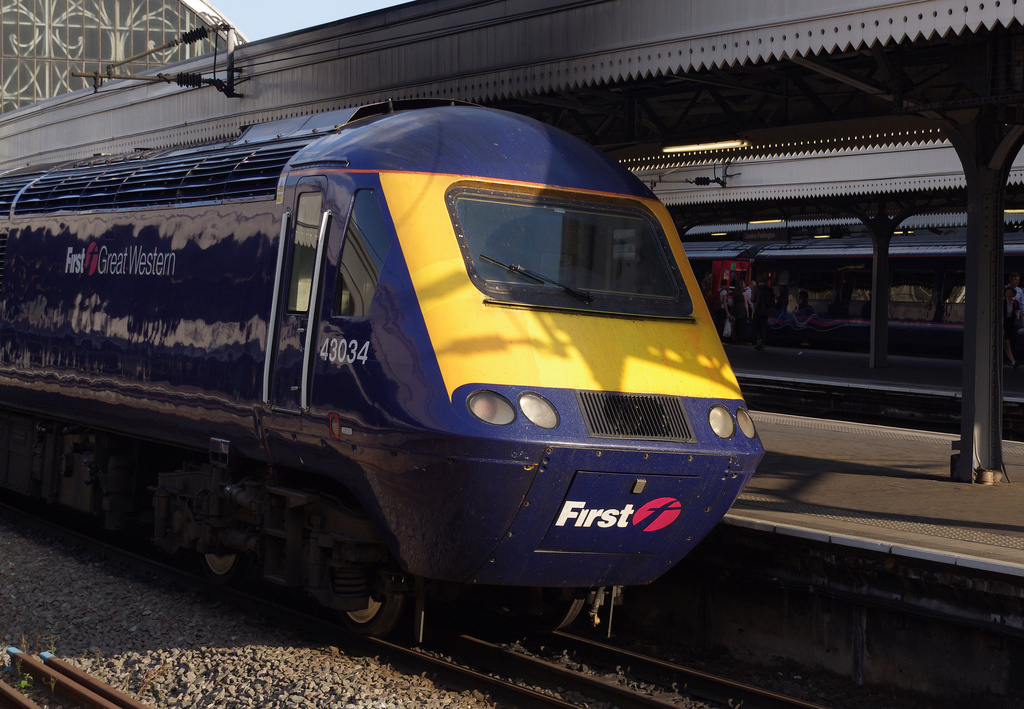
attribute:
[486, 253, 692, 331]
wiper — black 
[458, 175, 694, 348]
windscreen — rectangular 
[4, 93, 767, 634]
train — yellow, blue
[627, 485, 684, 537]
emblem — red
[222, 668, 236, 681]
rock — small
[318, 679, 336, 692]
rock — small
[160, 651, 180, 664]
rock — small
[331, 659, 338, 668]
rock — small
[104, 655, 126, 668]
rock — small